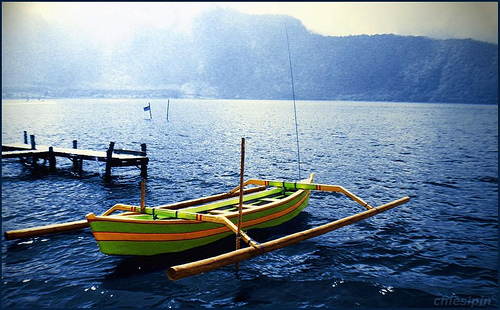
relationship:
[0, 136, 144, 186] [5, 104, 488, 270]
boat dock in water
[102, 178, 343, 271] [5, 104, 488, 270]
boat in water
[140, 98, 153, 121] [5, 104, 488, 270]
bouy in water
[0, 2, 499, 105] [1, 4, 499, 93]
hills in background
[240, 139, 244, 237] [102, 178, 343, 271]
pole on boat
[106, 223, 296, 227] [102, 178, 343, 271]
stripe on boat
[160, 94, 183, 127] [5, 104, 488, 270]
pole in water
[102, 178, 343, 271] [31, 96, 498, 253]
boat on sea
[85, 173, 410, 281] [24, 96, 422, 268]
boat in river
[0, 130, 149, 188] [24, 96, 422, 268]
boat dock on river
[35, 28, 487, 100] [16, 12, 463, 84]
hills in distance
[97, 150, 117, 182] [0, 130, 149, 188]
post on boat dock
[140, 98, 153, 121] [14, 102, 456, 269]
bouy in lake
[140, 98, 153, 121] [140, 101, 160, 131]
bouy on post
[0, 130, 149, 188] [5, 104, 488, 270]
boat dock in water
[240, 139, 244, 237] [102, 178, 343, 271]
pole next to boat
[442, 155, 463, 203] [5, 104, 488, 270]
waves in water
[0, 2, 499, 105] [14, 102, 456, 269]
hills across lake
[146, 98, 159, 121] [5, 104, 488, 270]
bouy in water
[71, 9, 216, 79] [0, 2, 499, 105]
fog in hills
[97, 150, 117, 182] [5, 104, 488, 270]
post on water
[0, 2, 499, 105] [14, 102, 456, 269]
hills behind lake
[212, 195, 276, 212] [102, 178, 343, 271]
boards on boat